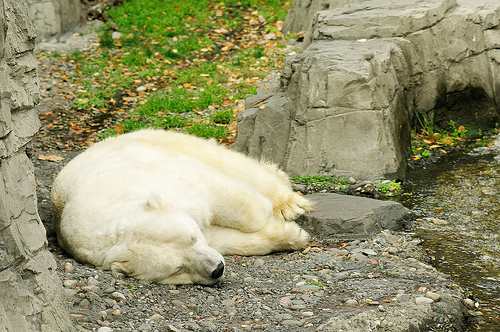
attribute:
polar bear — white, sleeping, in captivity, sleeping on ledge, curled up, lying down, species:
[57, 128, 313, 285]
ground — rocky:
[7, 3, 495, 331]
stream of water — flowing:
[397, 140, 499, 332]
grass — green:
[38, 3, 306, 152]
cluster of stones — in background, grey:
[2, 3, 74, 329]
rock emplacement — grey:
[239, 6, 497, 201]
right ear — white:
[107, 256, 135, 279]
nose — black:
[210, 258, 230, 280]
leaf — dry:
[142, 56, 158, 65]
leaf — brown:
[249, 17, 260, 28]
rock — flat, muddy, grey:
[290, 190, 412, 248]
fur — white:
[55, 124, 307, 283]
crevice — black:
[393, 84, 494, 178]